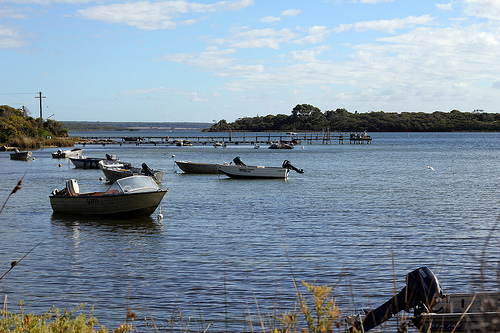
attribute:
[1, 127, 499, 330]
water — calm, large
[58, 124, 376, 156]
dock — wooden, long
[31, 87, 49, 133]
telephone pole — brown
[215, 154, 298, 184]
boat — white, small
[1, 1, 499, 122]
sky — blue, cloudy, bright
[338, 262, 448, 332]
motor — black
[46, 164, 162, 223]
boat — white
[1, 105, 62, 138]
shrubs — green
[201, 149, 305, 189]
boat — white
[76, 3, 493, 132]
clouds — white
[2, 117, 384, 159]
dock — wooden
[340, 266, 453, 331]
boat motor — black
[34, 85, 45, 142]
pole — wooden, electrical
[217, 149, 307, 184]
boat — white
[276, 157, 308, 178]
motor — black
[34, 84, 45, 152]
pole — electrical